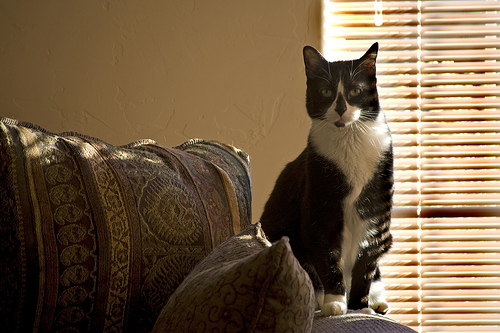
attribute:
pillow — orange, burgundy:
[34, 133, 282, 320]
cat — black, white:
[265, 60, 456, 297]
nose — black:
[329, 103, 359, 121]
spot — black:
[334, 89, 346, 101]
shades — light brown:
[342, 1, 499, 331]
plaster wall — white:
[83, 26, 183, 82]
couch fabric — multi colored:
[0, 118, 260, 329]